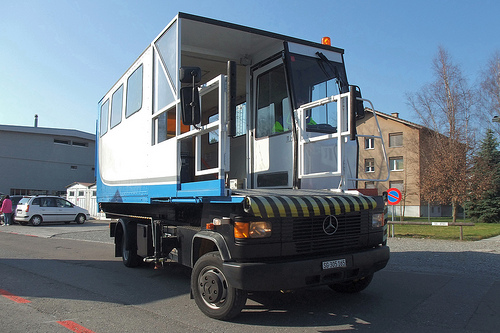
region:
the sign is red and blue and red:
[391, 190, 398, 206]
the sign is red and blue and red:
[387, 190, 399, 219]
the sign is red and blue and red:
[384, 191, 401, 208]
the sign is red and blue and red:
[392, 186, 401, 198]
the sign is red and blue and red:
[389, 194, 398, 211]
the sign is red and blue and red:
[390, 191, 396, 203]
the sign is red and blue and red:
[393, 184, 401, 214]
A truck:
[174, 59, 344, 321]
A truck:
[176, 79, 296, 234]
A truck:
[225, 157, 325, 327]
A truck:
[228, 99, 297, 256]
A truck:
[149, 124, 267, 319]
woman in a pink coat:
[0, 193, 15, 228]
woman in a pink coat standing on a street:
[0, 191, 18, 227]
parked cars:
[9, 190, 96, 227]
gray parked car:
[15, 193, 98, 225]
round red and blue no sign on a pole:
[381, 188, 405, 240]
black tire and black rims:
[188, 250, 246, 320]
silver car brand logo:
[321, 214, 339, 234]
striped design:
[246, 194, 385, 214]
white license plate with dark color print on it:
[318, 257, 355, 269]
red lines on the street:
[1, 275, 106, 330]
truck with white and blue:
[82, 36, 425, 276]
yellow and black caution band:
[227, 188, 407, 221]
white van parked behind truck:
[6, 178, 123, 260]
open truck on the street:
[126, 14, 368, 210]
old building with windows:
[357, 91, 477, 247]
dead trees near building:
[407, 43, 478, 234]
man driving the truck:
[264, 91, 356, 168]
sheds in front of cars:
[53, 169, 114, 233]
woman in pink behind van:
[0, 185, 20, 234]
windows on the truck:
[94, 89, 164, 144]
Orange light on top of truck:
[318, 30, 335, 47]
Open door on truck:
[293, 86, 353, 183]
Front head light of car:
[230, 215, 278, 245]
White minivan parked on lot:
[16, 190, 93, 232]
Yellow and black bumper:
[241, 191, 377, 215]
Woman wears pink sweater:
[4, 198, 13, 213]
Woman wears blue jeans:
[3, 213, 13, 223]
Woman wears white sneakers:
[0, 220, 13, 229]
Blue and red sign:
[381, 178, 404, 212]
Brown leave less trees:
[413, 44, 494, 209]